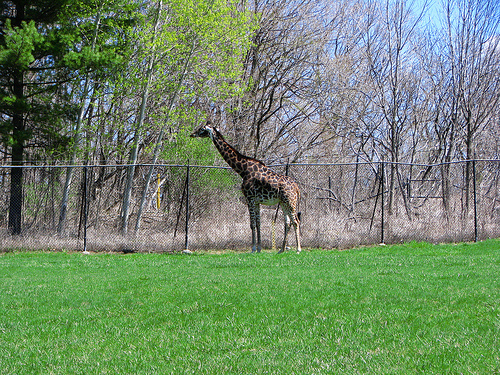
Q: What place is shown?
A: It is a zoo.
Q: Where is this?
A: This is at the zoo.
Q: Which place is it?
A: It is a zoo.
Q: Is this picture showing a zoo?
A: Yes, it is showing a zoo.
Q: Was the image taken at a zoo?
A: Yes, it was taken in a zoo.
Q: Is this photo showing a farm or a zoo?
A: It is showing a zoo.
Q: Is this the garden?
A: No, it is the zoo.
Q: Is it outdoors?
A: Yes, it is outdoors.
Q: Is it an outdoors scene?
A: Yes, it is outdoors.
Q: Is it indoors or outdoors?
A: It is outdoors.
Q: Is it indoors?
A: No, it is outdoors.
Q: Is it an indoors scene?
A: No, it is outdoors.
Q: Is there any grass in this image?
A: Yes, there is grass.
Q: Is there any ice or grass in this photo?
A: Yes, there is grass.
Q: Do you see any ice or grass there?
A: Yes, there is grass.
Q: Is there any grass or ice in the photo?
A: Yes, there is grass.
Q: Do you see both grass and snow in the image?
A: No, there is grass but no snow.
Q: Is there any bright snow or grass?
A: Yes, there is bright grass.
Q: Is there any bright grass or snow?
A: Yes, there is bright grass.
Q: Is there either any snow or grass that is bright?
A: Yes, the grass is bright.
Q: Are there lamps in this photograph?
A: No, there are no lamps.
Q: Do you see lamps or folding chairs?
A: No, there are no lamps or folding chairs.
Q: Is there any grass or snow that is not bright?
A: No, there is grass but it is bright.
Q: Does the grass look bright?
A: Yes, the grass is bright.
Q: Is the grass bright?
A: Yes, the grass is bright.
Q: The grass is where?
A: The grass is on the ground.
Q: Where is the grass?
A: The grass is on the ground.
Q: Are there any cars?
A: No, there are no cars.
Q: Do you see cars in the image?
A: No, there are no cars.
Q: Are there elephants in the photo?
A: No, there are no elephants.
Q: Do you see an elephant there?
A: No, there are no elephants.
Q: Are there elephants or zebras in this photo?
A: No, there are no elephants or zebras.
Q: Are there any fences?
A: Yes, there is a fence.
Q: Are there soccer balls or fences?
A: Yes, there is a fence.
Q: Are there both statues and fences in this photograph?
A: No, there is a fence but no statues.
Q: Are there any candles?
A: No, there are no candles.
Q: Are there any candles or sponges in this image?
A: No, there are no candles or sponges.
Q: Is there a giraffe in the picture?
A: Yes, there is a giraffe.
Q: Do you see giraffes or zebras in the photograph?
A: Yes, there is a giraffe.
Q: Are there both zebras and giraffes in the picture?
A: No, there is a giraffe but no zebras.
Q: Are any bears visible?
A: No, there are no bears.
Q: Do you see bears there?
A: No, there are no bears.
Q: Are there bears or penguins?
A: No, there are no bears or penguins.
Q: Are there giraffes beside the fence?
A: Yes, there is a giraffe beside the fence.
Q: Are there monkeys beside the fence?
A: No, there is a giraffe beside the fence.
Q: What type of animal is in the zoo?
A: The animal is a giraffe.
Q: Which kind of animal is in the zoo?
A: The animal is a giraffe.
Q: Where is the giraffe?
A: The giraffe is in the zoo.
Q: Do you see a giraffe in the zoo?
A: Yes, there is a giraffe in the zoo.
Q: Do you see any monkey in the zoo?
A: No, there is a giraffe in the zoo.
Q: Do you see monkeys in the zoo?
A: No, there is a giraffe in the zoo.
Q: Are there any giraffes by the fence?
A: Yes, there is a giraffe by the fence.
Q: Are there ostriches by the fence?
A: No, there is a giraffe by the fence.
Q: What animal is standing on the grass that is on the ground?
A: The giraffe is standing on the grass.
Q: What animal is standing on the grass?
A: The giraffe is standing on the grass.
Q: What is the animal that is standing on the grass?
A: The animal is a giraffe.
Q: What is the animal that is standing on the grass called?
A: The animal is a giraffe.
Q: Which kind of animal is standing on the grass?
A: The animal is a giraffe.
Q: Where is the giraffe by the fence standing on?
A: The giraffe is standing on the grass.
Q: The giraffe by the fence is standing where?
A: The giraffe is standing on the grass.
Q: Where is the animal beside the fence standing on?
A: The giraffe is standing on the grass.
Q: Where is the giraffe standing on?
A: The giraffe is standing on the grass.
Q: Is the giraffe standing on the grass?
A: Yes, the giraffe is standing on the grass.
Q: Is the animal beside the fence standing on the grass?
A: Yes, the giraffe is standing on the grass.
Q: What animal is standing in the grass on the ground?
A: The giraffe is standing in the grass.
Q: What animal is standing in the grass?
A: The giraffe is standing in the grass.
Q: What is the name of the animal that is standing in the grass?
A: The animal is a giraffe.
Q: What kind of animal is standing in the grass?
A: The animal is a giraffe.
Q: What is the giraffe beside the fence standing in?
A: The giraffe is standing in the grass.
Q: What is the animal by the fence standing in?
A: The giraffe is standing in the grass.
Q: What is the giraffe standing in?
A: The giraffe is standing in the grass.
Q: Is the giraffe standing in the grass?
A: Yes, the giraffe is standing in the grass.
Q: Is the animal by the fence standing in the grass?
A: Yes, the giraffe is standing in the grass.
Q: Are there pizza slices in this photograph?
A: No, there are no pizza slices.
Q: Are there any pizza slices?
A: No, there are no pizza slices.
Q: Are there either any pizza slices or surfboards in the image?
A: No, there are no pizza slices or surfboards.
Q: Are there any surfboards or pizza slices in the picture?
A: No, there are no pizza slices or surfboards.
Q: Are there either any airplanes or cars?
A: No, there are no cars or airplanes.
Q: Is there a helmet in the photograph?
A: No, there are no helmets.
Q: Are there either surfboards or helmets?
A: No, there are no helmets or surfboards.